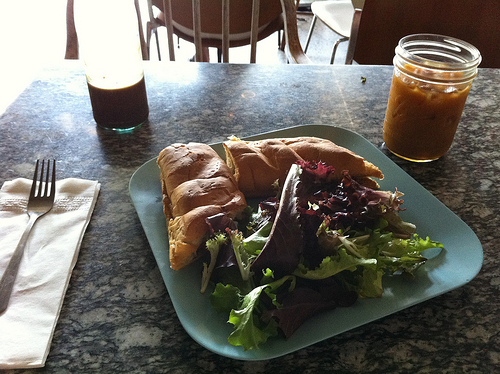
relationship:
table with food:
[1, 53, 499, 371] [155, 134, 446, 353]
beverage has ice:
[383, 34, 477, 163] [448, 86, 460, 96]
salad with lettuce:
[243, 200, 394, 272] [249, 149, 318, 274]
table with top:
[1, 53, 499, 371] [4, 57, 484, 366]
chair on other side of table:
[55, 5, 325, 61] [1, 53, 499, 371]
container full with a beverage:
[381, 33, 483, 164] [383, 59, 471, 159]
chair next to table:
[55, 5, 325, 61] [1, 53, 499, 371]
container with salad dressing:
[81, 11, 155, 132] [81, 56, 151, 132]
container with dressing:
[381, 33, 483, 164] [377, 60, 482, 176]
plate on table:
[101, 124, 498, 361] [1, 53, 499, 371]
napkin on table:
[0, 176, 102, 371] [1, 53, 499, 371]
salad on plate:
[197, 160, 445, 353] [101, 124, 498, 361]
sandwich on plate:
[156, 135, 386, 271] [126, 121, 485, 363]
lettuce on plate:
[198, 157, 447, 350] [126, 121, 485, 363]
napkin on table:
[6, 175, 77, 328] [16, 57, 473, 344]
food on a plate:
[170, 138, 430, 286] [126, 121, 485, 363]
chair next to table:
[62, 0, 362, 63] [1, 53, 499, 371]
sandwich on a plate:
[150, 135, 255, 271] [101, 124, 498, 361]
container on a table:
[381, 33, 483, 164] [1, 53, 499, 371]